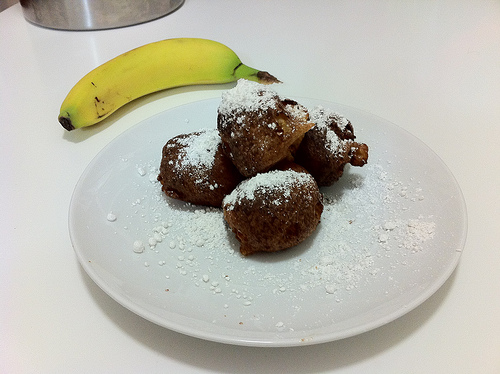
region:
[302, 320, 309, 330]
the plate is white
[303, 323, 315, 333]
the plate is white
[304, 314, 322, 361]
the plate is white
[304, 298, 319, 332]
the plate is white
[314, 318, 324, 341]
the plate is white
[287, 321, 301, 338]
the plate is white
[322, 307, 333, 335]
the plate is white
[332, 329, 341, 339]
the plate is white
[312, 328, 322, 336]
the plate is white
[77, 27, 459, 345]
breakfast items on counter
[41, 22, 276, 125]
yellow banana on counter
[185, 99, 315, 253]
donuts on white plate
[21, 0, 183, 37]
silver container in corner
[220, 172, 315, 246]
piece of donut on plate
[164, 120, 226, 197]
donut on white plate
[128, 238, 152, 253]
confectioner's sugar on plate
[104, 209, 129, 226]
confectioner's sugar on plate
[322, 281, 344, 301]
confectioner's sugar on plate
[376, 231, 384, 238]
confectioner's sugar on plate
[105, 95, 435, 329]
dessert is covered in powder sugar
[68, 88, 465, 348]
circular white plate under dessert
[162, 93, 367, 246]
brown chocolate dessert balls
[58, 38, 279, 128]
yellow banana behind plate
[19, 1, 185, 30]
metal container is top left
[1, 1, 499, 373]
white table top under plate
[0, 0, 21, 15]
edge of table shown top right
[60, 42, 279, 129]
banana has green spots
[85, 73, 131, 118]
banana has brown spots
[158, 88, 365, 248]
four dessert balls shown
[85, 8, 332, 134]
banana on white table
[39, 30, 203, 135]
banana on white table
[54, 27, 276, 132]
a ripe banana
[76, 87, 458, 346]
a white plate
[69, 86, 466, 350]
a round plate with food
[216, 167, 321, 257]
a brown piece of food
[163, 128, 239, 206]
a brown piece of food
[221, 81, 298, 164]
a brown piece of food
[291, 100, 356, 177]
a brown piece of food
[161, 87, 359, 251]
food dusted with powered sugar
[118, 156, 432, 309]
plate dusted with powdered sugar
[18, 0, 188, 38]
a metal cannister